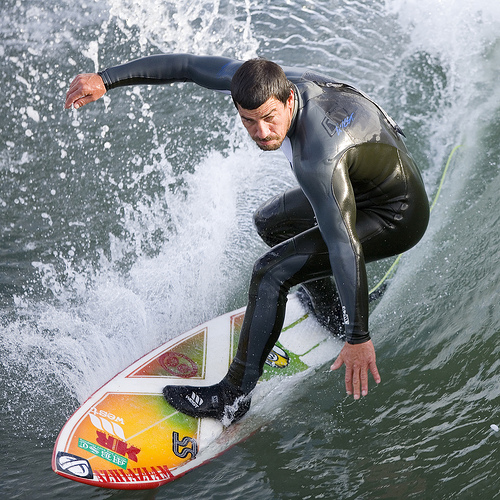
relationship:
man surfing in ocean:
[56, 44, 439, 427] [6, 5, 498, 499]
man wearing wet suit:
[56, 44, 439, 427] [100, 49, 436, 393]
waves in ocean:
[407, 8, 500, 374] [6, 5, 498, 499]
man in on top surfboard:
[56, 44, 439, 427] [45, 291, 370, 495]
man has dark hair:
[56, 44, 439, 427] [229, 57, 298, 112]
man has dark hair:
[56, 44, 439, 427] [222, 52, 298, 107]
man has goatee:
[56, 44, 439, 427] [249, 131, 282, 154]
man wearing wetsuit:
[56, 44, 439, 427] [100, 49, 436, 393]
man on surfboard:
[56, 44, 439, 427] [45, 291, 370, 495]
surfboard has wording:
[45, 291, 370, 495] [92, 460, 175, 489]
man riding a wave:
[56, 44, 439, 427] [1, 141, 239, 343]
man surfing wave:
[56, 44, 439, 427] [1, 141, 239, 343]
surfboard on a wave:
[45, 291, 370, 495] [6, 5, 498, 499]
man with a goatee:
[56, 44, 439, 427] [249, 131, 282, 154]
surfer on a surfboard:
[56, 44, 439, 427] [45, 291, 370, 495]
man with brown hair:
[56, 44, 439, 427] [222, 52, 298, 107]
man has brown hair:
[56, 44, 439, 427] [222, 52, 298, 107]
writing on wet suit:
[334, 112, 356, 137] [100, 49, 436, 393]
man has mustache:
[56, 44, 439, 427] [249, 131, 282, 154]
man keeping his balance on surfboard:
[56, 44, 439, 427] [47, 280, 359, 486]